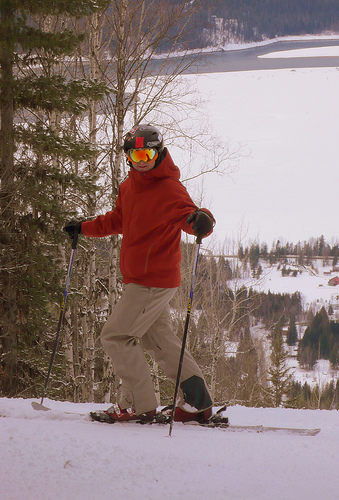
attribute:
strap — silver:
[111, 398, 121, 416]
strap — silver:
[120, 399, 136, 418]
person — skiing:
[60, 123, 215, 421]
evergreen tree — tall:
[0, 2, 110, 402]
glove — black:
[183, 206, 215, 247]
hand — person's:
[184, 206, 215, 245]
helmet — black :
[121, 123, 163, 172]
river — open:
[3, 30, 336, 90]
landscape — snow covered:
[2, 2, 335, 498]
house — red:
[323, 271, 337, 288]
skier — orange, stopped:
[63, 121, 216, 425]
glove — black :
[63, 217, 82, 239]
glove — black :
[185, 208, 215, 241]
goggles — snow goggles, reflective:
[127, 144, 157, 162]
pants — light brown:
[99, 279, 214, 409]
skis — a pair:
[30, 396, 322, 437]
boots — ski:
[107, 368, 221, 443]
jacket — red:
[80, 156, 195, 288]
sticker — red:
[131, 135, 146, 149]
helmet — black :
[122, 119, 164, 158]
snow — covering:
[2, 394, 338, 499]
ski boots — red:
[97, 393, 214, 428]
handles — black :
[59, 219, 213, 251]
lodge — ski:
[249, 259, 337, 310]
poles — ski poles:
[175, 242, 277, 455]